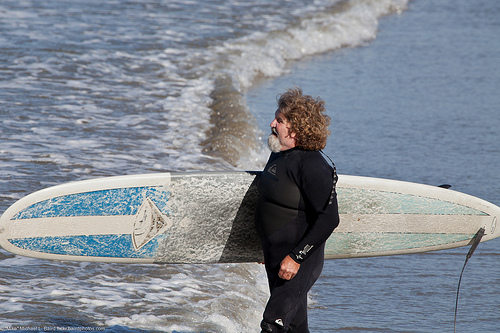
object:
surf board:
[0, 170, 500, 265]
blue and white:
[6, 186, 173, 260]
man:
[255, 85, 340, 333]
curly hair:
[275, 85, 332, 151]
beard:
[267, 134, 282, 153]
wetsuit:
[254, 145, 341, 333]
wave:
[152, 0, 409, 170]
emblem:
[131, 196, 171, 251]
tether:
[453, 226, 486, 330]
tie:
[399, 180, 499, 258]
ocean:
[0, 0, 409, 333]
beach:
[244, 0, 500, 333]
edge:
[170, 170, 263, 178]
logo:
[267, 164, 277, 177]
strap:
[319, 149, 337, 207]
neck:
[271, 145, 300, 155]